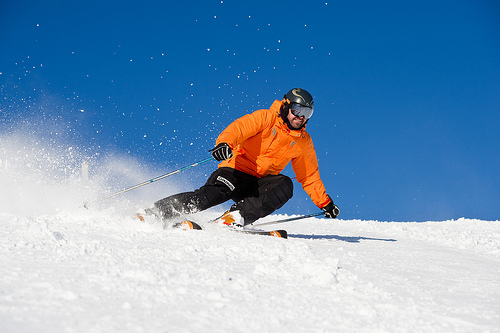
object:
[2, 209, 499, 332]
hill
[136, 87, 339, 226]
skier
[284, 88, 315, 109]
helmet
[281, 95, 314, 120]
goggles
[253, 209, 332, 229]
pole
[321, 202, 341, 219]
left hand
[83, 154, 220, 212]
pole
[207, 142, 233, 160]
right hand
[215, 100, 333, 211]
coat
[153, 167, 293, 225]
pants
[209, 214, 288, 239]
skies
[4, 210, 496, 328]
snow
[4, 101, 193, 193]
snow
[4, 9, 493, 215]
air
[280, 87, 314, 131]
head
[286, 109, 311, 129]
face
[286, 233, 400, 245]
shadow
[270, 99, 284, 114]
hood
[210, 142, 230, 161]
glove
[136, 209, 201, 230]
feet